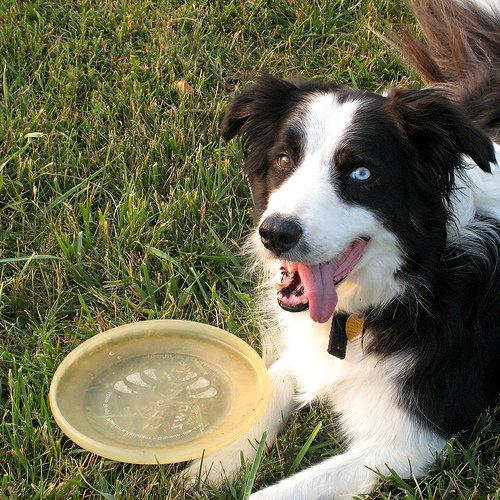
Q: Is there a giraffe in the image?
A: No, there are no giraffes.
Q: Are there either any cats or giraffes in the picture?
A: No, there are no giraffes or cats.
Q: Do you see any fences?
A: No, there are no fences.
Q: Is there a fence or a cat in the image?
A: No, there are no fences or cats.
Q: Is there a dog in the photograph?
A: Yes, there is a dog.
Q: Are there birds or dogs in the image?
A: Yes, there is a dog.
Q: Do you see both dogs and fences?
A: No, there is a dog but no fences.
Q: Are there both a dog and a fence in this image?
A: No, there is a dog but no fences.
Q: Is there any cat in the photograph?
A: No, there are no cats.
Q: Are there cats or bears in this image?
A: No, there are no cats or bears.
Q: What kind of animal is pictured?
A: The animal is a dog.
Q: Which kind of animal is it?
A: The animal is a dog.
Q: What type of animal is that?
A: This is a dog.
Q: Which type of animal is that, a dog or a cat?
A: This is a dog.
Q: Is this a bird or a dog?
A: This is a dog.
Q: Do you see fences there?
A: No, there are no fences.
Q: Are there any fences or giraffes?
A: No, there are no fences or giraffes.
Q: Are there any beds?
A: No, there are no beds.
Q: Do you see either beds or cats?
A: No, there are no beds or cats.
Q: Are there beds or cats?
A: No, there are no beds or cats.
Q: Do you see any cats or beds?
A: No, there are no beds or cats.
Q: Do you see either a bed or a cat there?
A: No, there are no beds or cats.